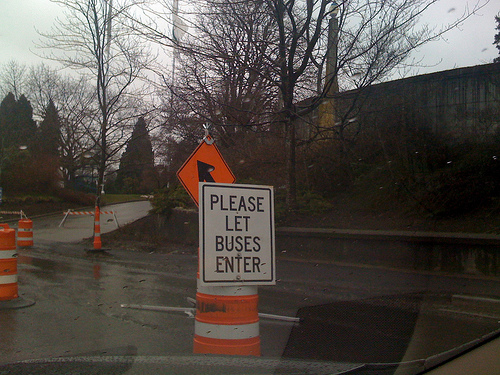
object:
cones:
[0, 222, 20, 302]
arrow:
[197, 159, 217, 185]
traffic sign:
[167, 116, 278, 209]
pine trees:
[35, 0, 165, 194]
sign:
[198, 182, 276, 287]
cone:
[89, 206, 106, 253]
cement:
[27, 199, 96, 242]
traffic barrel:
[192, 247, 263, 357]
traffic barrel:
[17, 218, 34, 246]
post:
[317, 100, 334, 142]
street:
[3, 233, 500, 373]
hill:
[157, 142, 500, 234]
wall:
[259, 60, 497, 231]